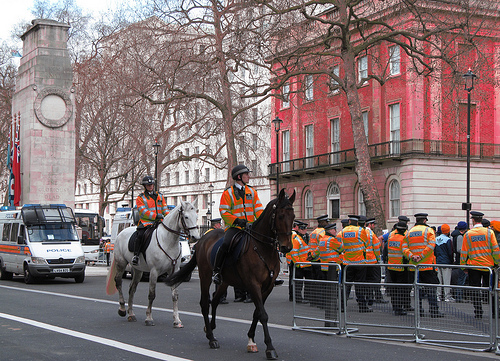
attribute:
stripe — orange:
[0, 244, 33, 256]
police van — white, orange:
[1, 203, 87, 283]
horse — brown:
[166, 187, 295, 360]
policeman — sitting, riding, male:
[212, 165, 265, 286]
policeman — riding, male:
[131, 176, 171, 266]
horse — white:
[106, 196, 202, 329]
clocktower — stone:
[11, 19, 75, 215]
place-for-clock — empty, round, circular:
[32, 84, 77, 128]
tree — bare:
[249, 1, 498, 236]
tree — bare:
[126, 1, 326, 191]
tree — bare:
[74, 1, 271, 218]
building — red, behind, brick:
[270, 1, 500, 233]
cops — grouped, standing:
[459, 211, 500, 319]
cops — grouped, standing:
[408, 213, 443, 318]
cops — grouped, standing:
[318, 223, 344, 328]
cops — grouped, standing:
[386, 222, 408, 316]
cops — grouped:
[295, 223, 308, 245]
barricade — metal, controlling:
[291, 261, 500, 351]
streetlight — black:
[459, 68, 477, 228]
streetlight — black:
[270, 115, 283, 197]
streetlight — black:
[151, 140, 162, 192]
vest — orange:
[218, 185, 263, 230]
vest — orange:
[136, 191, 169, 227]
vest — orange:
[460, 228, 500, 273]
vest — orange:
[401, 225, 439, 271]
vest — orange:
[387, 234, 406, 272]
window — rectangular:
[388, 101, 401, 158]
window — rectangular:
[329, 118, 341, 165]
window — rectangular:
[306, 124, 314, 169]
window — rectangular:
[283, 128, 289, 170]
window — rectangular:
[389, 45, 401, 77]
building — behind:
[75, 15, 271, 236]